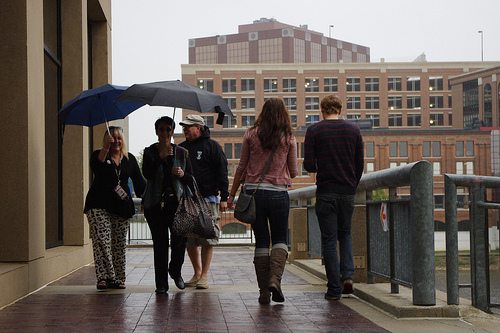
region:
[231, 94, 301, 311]
woman with long dark hair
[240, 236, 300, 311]
woman's tall brown boots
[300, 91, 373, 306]
man in long sleeved striped shirt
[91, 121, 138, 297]
blond woman with animal print pants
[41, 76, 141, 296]
woman holding blue umbrella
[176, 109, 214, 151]
man in grey cap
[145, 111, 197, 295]
woman with short hair and glasses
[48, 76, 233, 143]
two open umbrellas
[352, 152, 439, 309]
modern metal railing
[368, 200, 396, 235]
sign with red directional arrow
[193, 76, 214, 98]
a window in a building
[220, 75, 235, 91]
a window in a building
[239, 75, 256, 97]
a window in a building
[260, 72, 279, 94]
a window in a building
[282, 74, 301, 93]
a window in a building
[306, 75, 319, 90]
a window in a building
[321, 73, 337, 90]
a window in a building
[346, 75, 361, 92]
a window in a building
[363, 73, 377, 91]
a window in a building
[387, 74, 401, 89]
a window in a building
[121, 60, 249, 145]
lady holding black umbrella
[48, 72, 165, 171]
lady holding blue umbrella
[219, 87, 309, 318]
bag across ladies shoulder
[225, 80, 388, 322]
man and lady walking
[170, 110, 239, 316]
man wearing grey cap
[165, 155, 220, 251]
lady holding big bag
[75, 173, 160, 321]
lady wearing printed pants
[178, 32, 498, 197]
buildings in the background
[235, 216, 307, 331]
lady wearing brown boots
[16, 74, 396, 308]
people walking on harbor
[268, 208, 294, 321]
the leg of a person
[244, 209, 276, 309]
the leg of a person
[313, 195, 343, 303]
the leg of a person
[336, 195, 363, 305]
the leg of a person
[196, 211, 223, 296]
the leg of a person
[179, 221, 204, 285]
the leg of a person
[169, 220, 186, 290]
the leg of a person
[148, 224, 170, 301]
the leg of a person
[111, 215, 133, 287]
the leg of a person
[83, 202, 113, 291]
the leg of a person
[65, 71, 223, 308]
two people holding umbrellas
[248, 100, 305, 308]
girl with knee high boots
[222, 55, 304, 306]
girl with dark colored purse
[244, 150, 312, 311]
girl wearing blue jeans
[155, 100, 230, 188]
man wearing ball cap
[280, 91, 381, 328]
man in blue jeans walking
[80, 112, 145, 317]
blonde woman in black shirt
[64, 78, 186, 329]
blonde woman with blue umbrella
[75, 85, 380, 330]
five people walking in rain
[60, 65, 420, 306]
five people walking on sidewalk